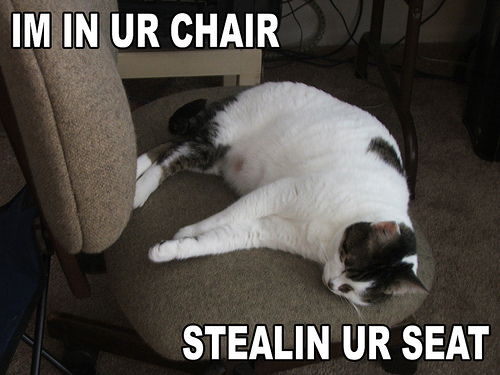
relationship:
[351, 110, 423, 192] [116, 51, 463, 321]
spot on cat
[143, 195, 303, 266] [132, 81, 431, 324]
front legs on bear cub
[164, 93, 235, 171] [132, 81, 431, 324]
spots on bear cub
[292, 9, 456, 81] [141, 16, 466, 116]
wires to table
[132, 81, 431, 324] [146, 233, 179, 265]
bear cub has paw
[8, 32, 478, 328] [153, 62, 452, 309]
chair has cat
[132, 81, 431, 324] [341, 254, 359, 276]
bear cub has eyes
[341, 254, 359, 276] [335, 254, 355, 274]
eyes has eye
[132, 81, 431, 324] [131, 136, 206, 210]
bear cub has back legs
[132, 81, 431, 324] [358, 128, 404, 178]
bear cub has spot